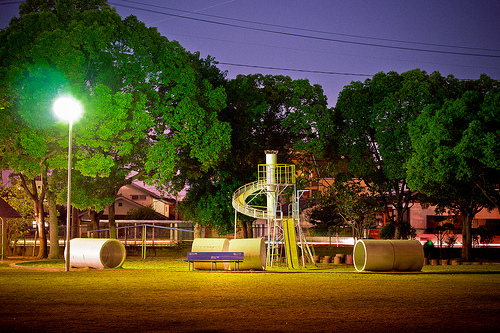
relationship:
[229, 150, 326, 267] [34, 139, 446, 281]
slide on playground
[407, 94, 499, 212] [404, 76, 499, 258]
leaves on tree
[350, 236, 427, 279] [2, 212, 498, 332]
tube on play area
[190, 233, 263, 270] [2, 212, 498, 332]
tube on play area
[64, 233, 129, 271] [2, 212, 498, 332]
tube on play area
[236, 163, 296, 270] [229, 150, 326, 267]
slide on slide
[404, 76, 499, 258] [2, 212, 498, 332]
tree beside play area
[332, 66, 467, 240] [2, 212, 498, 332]
tree beside play area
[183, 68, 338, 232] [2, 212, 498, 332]
tree beside play area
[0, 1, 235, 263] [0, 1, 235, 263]
tall tree beside tall tree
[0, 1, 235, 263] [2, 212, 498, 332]
tall tree beside play area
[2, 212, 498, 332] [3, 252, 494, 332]
play area covered with grass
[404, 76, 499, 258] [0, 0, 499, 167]
tree in sky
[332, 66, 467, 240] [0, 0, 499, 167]
tree in sky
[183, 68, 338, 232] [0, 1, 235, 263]
tree in tall tree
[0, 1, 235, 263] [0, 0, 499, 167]
tall tree in sky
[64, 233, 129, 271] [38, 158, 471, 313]
tube on playground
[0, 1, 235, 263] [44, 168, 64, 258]
tall tree has trunk